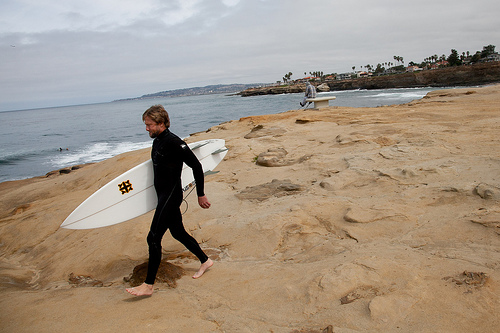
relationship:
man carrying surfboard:
[124, 104, 228, 298] [58, 137, 229, 232]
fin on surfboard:
[189, 139, 209, 151] [58, 137, 229, 232]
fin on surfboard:
[210, 147, 230, 155] [58, 137, 229, 232]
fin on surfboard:
[205, 169, 221, 176] [58, 137, 229, 232]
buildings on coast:
[291, 51, 499, 82] [0, 86, 480, 185]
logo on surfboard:
[117, 179, 133, 195] [58, 137, 229, 232]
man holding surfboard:
[124, 104, 228, 298] [58, 137, 229, 232]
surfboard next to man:
[58, 137, 229, 232] [124, 104, 228, 298]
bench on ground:
[306, 96, 339, 110] [1, 82, 498, 331]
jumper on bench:
[299, 80, 316, 107] [306, 96, 339, 110]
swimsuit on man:
[144, 127, 214, 286] [124, 104, 228, 298]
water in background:
[0, 85, 476, 184] [0, 0, 499, 183]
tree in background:
[287, 72, 291, 80] [0, 0, 499, 183]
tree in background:
[350, 65, 358, 72] [0, 0, 499, 183]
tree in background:
[392, 55, 397, 64] [0, 0, 499, 183]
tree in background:
[432, 55, 440, 61] [0, 0, 499, 183]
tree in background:
[466, 49, 470, 56] [0, 0, 499, 183]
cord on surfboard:
[179, 181, 198, 214] [58, 137, 229, 232]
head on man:
[140, 105, 173, 138] [124, 104, 228, 298]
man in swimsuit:
[124, 104, 228, 298] [144, 127, 214, 286]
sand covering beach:
[1, 82, 498, 331] [0, 81, 493, 326]